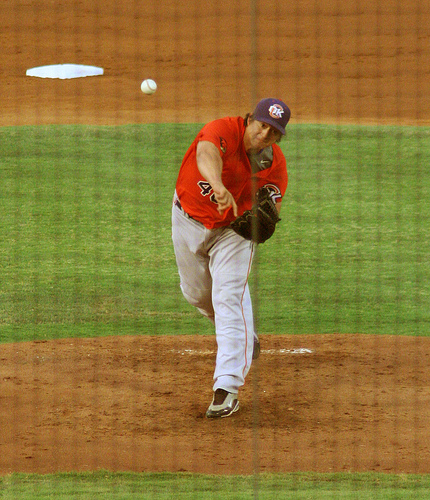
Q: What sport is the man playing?
A: Baseball.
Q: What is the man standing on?
A: Dirt.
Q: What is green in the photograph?
A: Grass.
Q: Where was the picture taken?
A: A baseball field.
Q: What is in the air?
A: Baseball.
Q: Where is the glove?
A: On the player's left hand.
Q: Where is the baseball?
A: In the air.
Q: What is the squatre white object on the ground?
A: A base.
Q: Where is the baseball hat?
A: On the player's head.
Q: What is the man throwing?
A: Baseball.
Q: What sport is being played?
A: Baseball.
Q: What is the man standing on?
A: Dirt.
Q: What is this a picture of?
A: A baseball player throwing a baseball.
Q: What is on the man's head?
A: Baseball hat.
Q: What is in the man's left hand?
A: A glove.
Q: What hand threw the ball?
A: The right hand.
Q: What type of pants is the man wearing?
A: Grey.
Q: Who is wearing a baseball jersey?
A: The pitcher.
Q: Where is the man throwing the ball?
A: Across the plate.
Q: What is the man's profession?
A: Baseball player.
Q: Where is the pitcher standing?
A: Pitcher's mound.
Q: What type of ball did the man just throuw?
A: Baseball.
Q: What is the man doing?
A: Playing baseball.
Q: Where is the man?
A: On the field.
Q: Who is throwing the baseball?
A: The man.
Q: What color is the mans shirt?
A: Red.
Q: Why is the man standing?
A: Throwing a baseball.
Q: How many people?
A: 1.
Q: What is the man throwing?
A: A baseball.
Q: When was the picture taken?
A: Daytime.